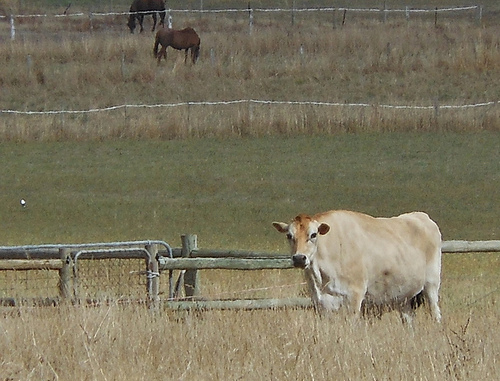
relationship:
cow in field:
[271, 210, 446, 332] [76, 252, 486, 348]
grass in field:
[0, 127, 498, 251] [16, 78, 417, 188]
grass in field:
[0, 127, 498, 251] [1, 130, 498, 252]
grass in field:
[0, 127, 498, 251] [14, 82, 484, 293]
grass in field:
[0, 127, 498, 251] [6, 0, 498, 379]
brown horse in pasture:
[153, 27, 201, 65] [2, 0, 499, 135]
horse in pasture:
[123, 1, 169, 31] [2, 0, 499, 135]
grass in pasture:
[0, 127, 498, 251] [0, 0, 499, 380]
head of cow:
[265, 206, 329, 267] [271, 210, 446, 332]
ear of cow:
[270, 221, 288, 232] [240, 157, 483, 335]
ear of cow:
[310, 220, 330, 240] [240, 157, 483, 335]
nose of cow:
[292, 253, 307, 263] [271, 197, 441, 322]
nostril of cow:
[290, 254, 310, 261] [271, 210, 446, 332]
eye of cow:
[309, 229, 320, 240] [271, 197, 441, 322]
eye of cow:
[287, 232, 293, 242] [271, 197, 441, 322]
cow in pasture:
[271, 210, 446, 332] [0, 229, 486, 331]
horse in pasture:
[123, 1, 169, 34] [7, 10, 494, 267]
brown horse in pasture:
[153, 27, 201, 65] [7, 10, 494, 267]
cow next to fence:
[271, 208, 446, 326] [2, 230, 499, 324]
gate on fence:
[73, 241, 160, 318] [21, 227, 316, 330]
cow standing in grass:
[271, 210, 446, 332] [0, 258, 499, 380]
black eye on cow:
[308, 230, 318, 239] [267, 207, 443, 319]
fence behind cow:
[118, 237, 272, 327] [262, 191, 482, 326]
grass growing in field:
[0, 127, 498, 251] [6, 0, 498, 379]